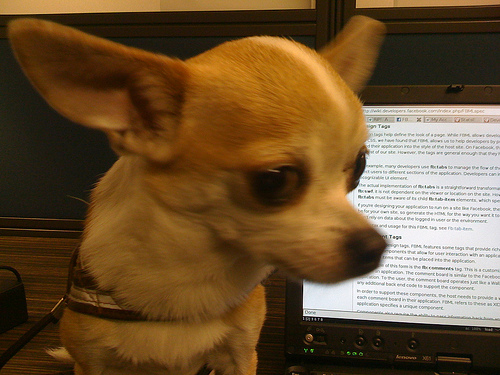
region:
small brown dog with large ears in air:
[15, 10, 382, 363]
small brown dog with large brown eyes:
[7, 21, 458, 319]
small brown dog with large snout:
[10, 11, 385, 356]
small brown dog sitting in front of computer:
[5, 16, 385, 371]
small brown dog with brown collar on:
[5, 10, 400, 350]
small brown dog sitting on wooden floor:
[0, 10, 380, 370]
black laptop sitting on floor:
[360, 70, 495, 370]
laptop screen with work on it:
[230, 20, 495, 370]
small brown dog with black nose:
[45, 25, 395, 370]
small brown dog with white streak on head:
[20, 5, 420, 355]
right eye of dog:
[345, 141, 370, 190]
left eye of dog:
[235, 160, 312, 206]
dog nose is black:
[336, 225, 391, 270]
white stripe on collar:
[69, 288, 106, 305]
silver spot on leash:
[47, 300, 67, 315]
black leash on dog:
[23, 323, 42, 342]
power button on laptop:
[300, 329, 317, 346]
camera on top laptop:
[434, 78, 471, 104]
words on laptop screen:
[409, 146, 462, 241]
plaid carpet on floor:
[26, 242, 53, 266]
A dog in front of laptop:
[2, 9, 387, 370]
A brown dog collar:
[18, 250, 175, 322]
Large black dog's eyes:
[248, 145, 373, 208]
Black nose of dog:
[349, 233, 385, 276]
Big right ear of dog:
[3, 15, 200, 151]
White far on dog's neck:
[93, 198, 257, 320]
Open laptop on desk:
[275, 84, 499, 372]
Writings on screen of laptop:
[346, 128, 498, 327]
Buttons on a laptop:
[301, 328, 423, 356]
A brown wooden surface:
[0, 234, 310, 374]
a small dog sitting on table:
[1, 1, 497, 373]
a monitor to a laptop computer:
[281, 81, 496, 372]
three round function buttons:
[350, 320, 415, 350]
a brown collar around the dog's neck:
[0, 241, 190, 371]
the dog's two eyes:
[242, 145, 364, 201]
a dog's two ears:
[5, 15, 385, 165]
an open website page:
[301, 105, 496, 325]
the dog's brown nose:
[347, 226, 388, 264]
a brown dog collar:
[0, 244, 186, 372]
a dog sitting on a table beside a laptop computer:
[2, 2, 498, 374]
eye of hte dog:
[245, 158, 307, 211]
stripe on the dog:
[294, 53, 351, 113]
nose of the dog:
[340, 226, 367, 271]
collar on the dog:
[80, 290, 208, 335]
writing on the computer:
[410, 210, 490, 311]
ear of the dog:
[15, 27, 163, 148]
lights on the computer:
[290, 335, 367, 357]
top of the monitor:
[370, 92, 491, 103]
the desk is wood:
[11, 237, 63, 272]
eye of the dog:
[240, 165, 303, 202]